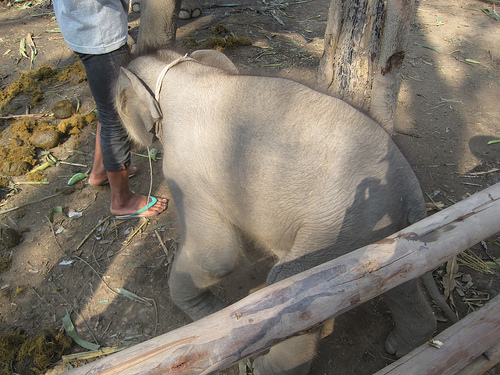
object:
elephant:
[109, 49, 457, 374]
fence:
[42, 181, 500, 374]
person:
[51, 0, 170, 220]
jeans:
[71, 41, 131, 172]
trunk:
[314, 0, 419, 137]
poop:
[0, 54, 98, 197]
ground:
[1, 0, 499, 374]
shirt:
[52, 0, 130, 56]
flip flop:
[114, 195, 168, 220]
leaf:
[461, 57, 493, 72]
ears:
[109, 66, 162, 147]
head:
[114, 48, 240, 149]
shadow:
[21, 213, 170, 351]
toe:
[385, 335, 408, 357]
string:
[153, 53, 196, 140]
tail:
[408, 203, 458, 324]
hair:
[125, 43, 183, 59]